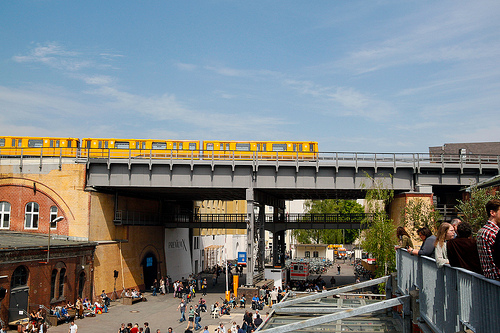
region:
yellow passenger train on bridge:
[15, 133, 317, 160]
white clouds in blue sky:
[21, 19, 78, 57]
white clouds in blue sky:
[21, 53, 79, 97]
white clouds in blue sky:
[88, 18, 139, 76]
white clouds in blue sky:
[100, 85, 155, 125]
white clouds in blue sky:
[174, 19, 236, 61]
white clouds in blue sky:
[202, 76, 296, 123]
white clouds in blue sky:
[284, 18, 336, 58]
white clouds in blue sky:
[335, 52, 369, 107]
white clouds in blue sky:
[401, 21, 456, 82]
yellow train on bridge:
[8, 135, 324, 157]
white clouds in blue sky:
[9, 9, 62, 58]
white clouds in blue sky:
[24, 68, 95, 108]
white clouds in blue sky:
[99, 75, 150, 106]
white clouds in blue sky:
[102, 26, 159, 66]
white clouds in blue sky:
[144, 90, 209, 132]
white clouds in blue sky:
[244, 58, 306, 106]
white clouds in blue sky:
[337, 13, 386, 60]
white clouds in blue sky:
[319, 64, 389, 107]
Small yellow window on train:
[81, 136, 96, 151]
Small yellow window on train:
[93, 136, 112, 156]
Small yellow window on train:
[111, 137, 139, 158]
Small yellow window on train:
[146, 139, 181, 159]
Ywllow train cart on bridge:
[195, 131, 329, 178]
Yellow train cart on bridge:
[80, 126, 200, 168]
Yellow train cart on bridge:
[1, 126, 326, 170]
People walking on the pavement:
[203, 293, 263, 330]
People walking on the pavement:
[153, 256, 193, 315]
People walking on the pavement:
[45, 301, 142, 328]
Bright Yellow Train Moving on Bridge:
[0, 118, 495, 198]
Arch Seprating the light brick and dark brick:
[3, 167, 84, 242]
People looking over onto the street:
[389, 184, 498, 329]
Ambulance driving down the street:
[284, 258, 312, 286]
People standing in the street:
[95, 275, 272, 331]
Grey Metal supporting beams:
[266, 278, 418, 330]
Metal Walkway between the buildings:
[113, 203, 398, 235]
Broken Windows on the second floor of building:
[1, 198, 63, 237]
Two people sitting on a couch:
[120, 289, 147, 306]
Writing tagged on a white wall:
[166, 238, 191, 252]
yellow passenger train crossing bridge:
[0, 135, 330, 196]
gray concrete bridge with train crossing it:
[67, 135, 498, 307]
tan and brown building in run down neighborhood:
[1, 159, 173, 309]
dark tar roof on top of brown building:
[0, 232, 100, 273]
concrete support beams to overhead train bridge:
[238, 180, 290, 290]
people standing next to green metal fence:
[390, 199, 498, 331]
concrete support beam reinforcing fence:
[262, 270, 426, 330]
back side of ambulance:
[285, 259, 312, 288]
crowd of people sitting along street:
[4, 274, 214, 331]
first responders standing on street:
[217, 283, 277, 310]